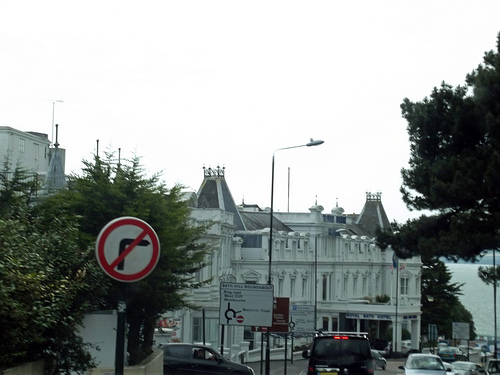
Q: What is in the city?
A: Cars.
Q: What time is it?
A: Daytime.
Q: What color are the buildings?
A: White.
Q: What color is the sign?
A: Black, white and red.